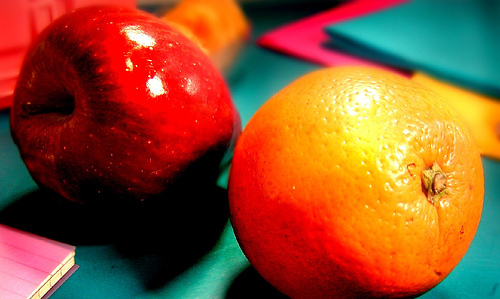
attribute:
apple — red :
[10, 4, 242, 223]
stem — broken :
[418, 160, 448, 202]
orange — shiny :
[211, 54, 491, 291]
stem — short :
[21, 97, 64, 118]